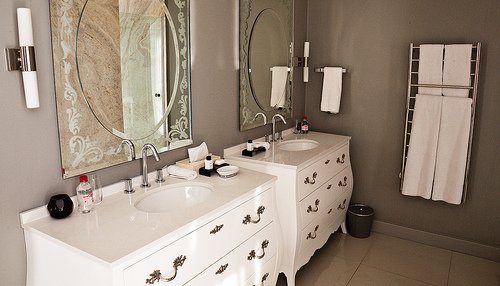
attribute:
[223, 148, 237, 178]
dish — white, soap dish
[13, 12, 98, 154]
light — white, long, silver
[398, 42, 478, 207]
towels — white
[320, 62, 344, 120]
towel — small, white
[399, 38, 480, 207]
towel rack — metal, aluminum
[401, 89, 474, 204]
towels — hanging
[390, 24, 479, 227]
towels — white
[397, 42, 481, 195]
rack — silver, long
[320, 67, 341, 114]
towel — white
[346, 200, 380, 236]
pail — small, garbage pail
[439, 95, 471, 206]
towel — white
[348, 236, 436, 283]
floor — tiled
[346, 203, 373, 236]
bin — small , dark 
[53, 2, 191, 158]
mirror — large, oval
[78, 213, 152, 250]
counter — white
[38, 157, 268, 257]
sink — matching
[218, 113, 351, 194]
sink — matching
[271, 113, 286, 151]
facet — silver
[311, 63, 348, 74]
holder — silver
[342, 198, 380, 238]
can — black